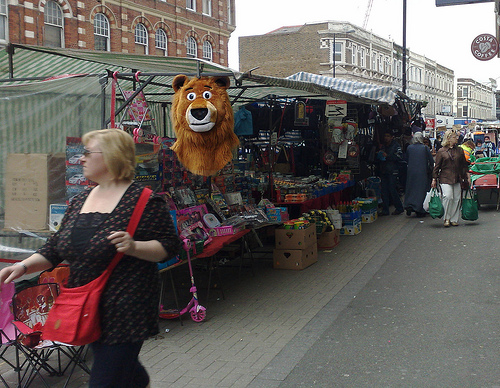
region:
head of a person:
[59, 109, 141, 193]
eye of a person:
[70, 137, 105, 159]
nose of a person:
[74, 148, 91, 163]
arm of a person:
[134, 223, 177, 260]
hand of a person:
[105, 225, 137, 253]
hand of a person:
[0, 256, 23, 291]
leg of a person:
[88, 320, 153, 385]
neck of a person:
[83, 177, 132, 187]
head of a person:
[435, 122, 465, 152]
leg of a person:
[436, 176, 454, 219]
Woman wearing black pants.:
[40, 118, 180, 387]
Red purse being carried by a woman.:
[43, 185, 163, 352]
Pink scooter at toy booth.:
[157, 223, 211, 325]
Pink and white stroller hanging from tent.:
[109, 60, 165, 147]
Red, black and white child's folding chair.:
[6, 278, 83, 378]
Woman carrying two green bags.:
[424, 125, 479, 230]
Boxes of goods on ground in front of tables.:
[272, 198, 390, 268]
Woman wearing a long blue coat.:
[399, 125, 431, 223]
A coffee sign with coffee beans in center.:
[471, 33, 498, 61]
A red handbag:
[41, 274, 112, 347]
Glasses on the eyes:
[73, 142, 103, 159]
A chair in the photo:
[9, 294, 53, 359]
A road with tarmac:
[359, 296, 455, 366]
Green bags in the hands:
[430, 181, 481, 226]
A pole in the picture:
[402, 11, 414, 73]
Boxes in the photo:
[270, 225, 320, 265]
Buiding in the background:
[274, 30, 334, 70]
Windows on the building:
[327, 37, 415, 87]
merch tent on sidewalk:
[167, 60, 377, 260]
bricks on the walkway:
[181, 343, 241, 378]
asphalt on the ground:
[423, 300, 450, 373]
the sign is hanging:
[451, 2, 498, 66]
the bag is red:
[35, 288, 101, 346]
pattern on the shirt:
[73, 229, 102, 253]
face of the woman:
[73, 143, 105, 178]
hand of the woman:
[107, 230, 129, 257]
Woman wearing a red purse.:
[1, 129, 180, 386]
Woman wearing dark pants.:
[0, 128, 183, 387]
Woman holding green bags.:
[431, 126, 473, 228]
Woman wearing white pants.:
[431, 126, 468, 227]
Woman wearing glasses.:
[1, 130, 181, 386]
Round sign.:
[470, 33, 499, 62]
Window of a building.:
[327, 38, 347, 65]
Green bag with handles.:
[461, 188, 480, 223]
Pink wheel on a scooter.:
[188, 304, 208, 324]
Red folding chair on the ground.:
[9, 281, 89, 386]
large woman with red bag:
[6, 115, 198, 383]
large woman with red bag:
[13, 112, 191, 385]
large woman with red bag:
[18, 119, 194, 383]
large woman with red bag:
[14, 118, 205, 383]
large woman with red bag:
[17, 110, 197, 379]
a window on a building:
[93, 13, 112, 50]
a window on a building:
[136, 17, 146, 53]